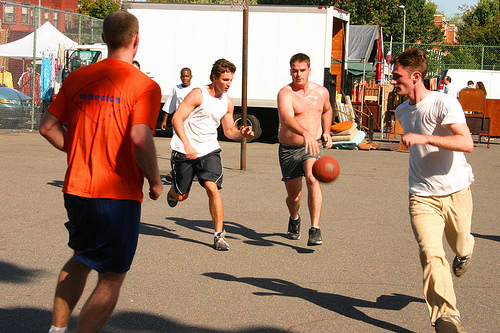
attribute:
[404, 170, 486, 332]
pants — brown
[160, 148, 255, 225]
shorts — black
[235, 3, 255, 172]
pole — rusty, metal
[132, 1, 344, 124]
truck — white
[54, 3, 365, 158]
van — black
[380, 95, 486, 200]
tshirt — white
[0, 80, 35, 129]
car — parked, blue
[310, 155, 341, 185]
basketball — brown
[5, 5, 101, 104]
fence — tall, chain link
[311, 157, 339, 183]
basketball — orange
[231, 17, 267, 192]
pole — wooden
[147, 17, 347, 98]
lorry — white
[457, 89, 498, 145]
furniture — brown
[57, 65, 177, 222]
shirt — orange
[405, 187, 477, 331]
pants — brown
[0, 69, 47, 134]
car — in the distance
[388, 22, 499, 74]
fence — green, metal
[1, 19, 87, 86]
tent — white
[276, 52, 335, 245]
man — shirtless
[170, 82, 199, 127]
shirt — white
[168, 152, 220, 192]
shorts — black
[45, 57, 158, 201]
shirt — orange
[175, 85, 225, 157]
tank top — white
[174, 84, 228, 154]
vest — white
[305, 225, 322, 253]
shoe — black, white, tennis